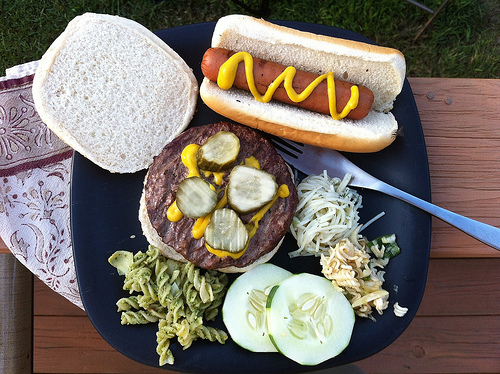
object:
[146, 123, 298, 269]
hamburger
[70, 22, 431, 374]
plate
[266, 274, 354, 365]
cucumber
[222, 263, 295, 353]
cucumber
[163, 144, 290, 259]
mustard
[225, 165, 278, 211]
pickle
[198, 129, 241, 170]
pickle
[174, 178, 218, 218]
pickle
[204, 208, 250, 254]
pickle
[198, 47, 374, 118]
hotdog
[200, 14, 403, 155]
bun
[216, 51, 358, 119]
mustard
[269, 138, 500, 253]
fork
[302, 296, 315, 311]
seed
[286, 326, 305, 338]
seed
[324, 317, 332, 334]
seed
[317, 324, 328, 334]
seed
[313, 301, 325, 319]
seed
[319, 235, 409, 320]
food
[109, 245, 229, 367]
pasta salad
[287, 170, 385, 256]
noodles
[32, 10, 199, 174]
bun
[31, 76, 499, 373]
table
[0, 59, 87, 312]
napkin